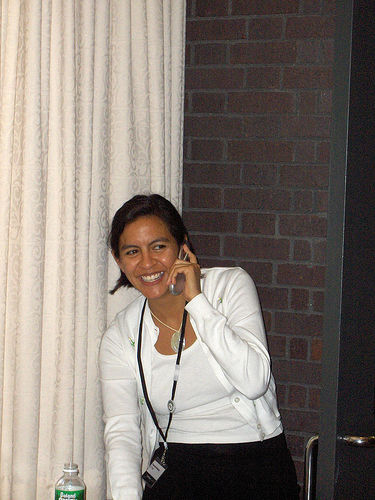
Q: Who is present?
A: A woman.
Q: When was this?
A: Daytime.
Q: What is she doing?
A: Talking on the phone.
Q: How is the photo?
A: Clear.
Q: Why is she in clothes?
A: To keep warm.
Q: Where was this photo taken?
A: In an office building.